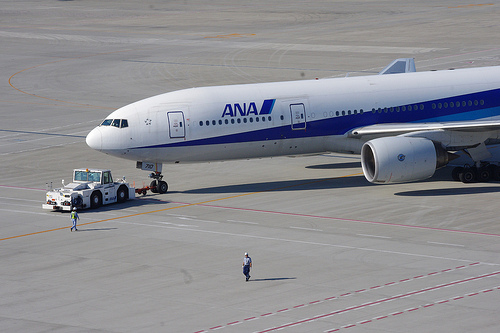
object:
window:
[335, 111, 340, 117]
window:
[408, 105, 413, 111]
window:
[167, 110, 187, 139]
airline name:
[220, 102, 258, 118]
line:
[197, 259, 500, 333]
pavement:
[1, 0, 497, 329]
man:
[69, 206, 79, 232]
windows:
[279, 115, 285, 121]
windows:
[342, 110, 346, 116]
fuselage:
[85, 55, 500, 182]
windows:
[100, 118, 128, 129]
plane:
[55, 56, 499, 185]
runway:
[1, 0, 500, 332]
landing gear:
[136, 161, 169, 194]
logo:
[222, 98, 277, 118]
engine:
[359, 134, 454, 184]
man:
[241, 252, 253, 281]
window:
[205, 120, 210, 126]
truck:
[41, 169, 135, 212]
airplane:
[84, 56, 500, 195]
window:
[211, 119, 218, 126]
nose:
[85, 127, 133, 157]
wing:
[342, 114, 500, 155]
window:
[236, 117, 241, 123]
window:
[256, 116, 260, 122]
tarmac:
[1, 0, 494, 330]